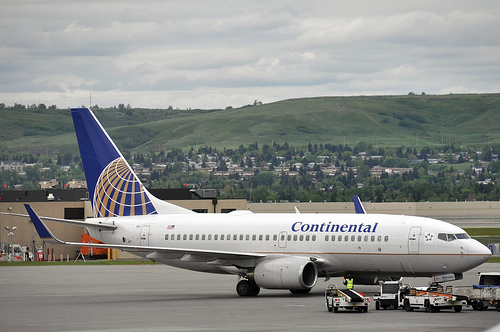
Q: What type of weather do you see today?
A: It is cloudy.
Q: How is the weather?
A: It is cloudy.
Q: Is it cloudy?
A: Yes, it is cloudy.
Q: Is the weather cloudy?
A: Yes, it is cloudy.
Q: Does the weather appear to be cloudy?
A: Yes, it is cloudy.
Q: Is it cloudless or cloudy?
A: It is cloudy.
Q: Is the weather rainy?
A: No, it is cloudy.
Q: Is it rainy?
A: No, it is cloudy.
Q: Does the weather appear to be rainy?
A: No, it is cloudy.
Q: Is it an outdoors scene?
A: Yes, it is outdoors.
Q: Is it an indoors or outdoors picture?
A: It is outdoors.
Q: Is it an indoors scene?
A: No, it is outdoors.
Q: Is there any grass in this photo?
A: Yes, there is grass.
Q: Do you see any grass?
A: Yes, there is grass.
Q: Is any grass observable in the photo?
A: Yes, there is grass.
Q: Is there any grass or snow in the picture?
A: Yes, there is grass.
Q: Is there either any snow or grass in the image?
A: Yes, there is grass.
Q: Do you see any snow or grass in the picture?
A: Yes, there is grass.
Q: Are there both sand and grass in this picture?
A: No, there is grass but no sand.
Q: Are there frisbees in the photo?
A: No, there are no frisbees.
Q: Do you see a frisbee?
A: No, there are no frisbees.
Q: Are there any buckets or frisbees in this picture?
A: No, there are no frisbees or buckets.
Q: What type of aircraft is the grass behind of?
A: The grass is behind the plane.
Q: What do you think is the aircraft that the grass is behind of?
A: The aircraft is an airplane.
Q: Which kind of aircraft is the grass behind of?
A: The grass is behind the plane.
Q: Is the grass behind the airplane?
A: Yes, the grass is behind the airplane.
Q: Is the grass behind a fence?
A: No, the grass is behind the airplane.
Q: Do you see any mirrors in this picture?
A: No, there are no mirrors.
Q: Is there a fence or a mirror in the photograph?
A: No, there are no mirrors or fences.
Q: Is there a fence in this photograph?
A: No, there are no fences.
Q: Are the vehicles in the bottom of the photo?
A: Yes, the vehicles are in the bottom of the image.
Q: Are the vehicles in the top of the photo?
A: No, the vehicles are in the bottom of the image.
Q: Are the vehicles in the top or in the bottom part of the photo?
A: The vehicles are in the bottom of the image.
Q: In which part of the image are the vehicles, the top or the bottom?
A: The vehicles are in the bottom of the image.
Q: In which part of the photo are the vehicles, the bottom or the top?
A: The vehicles are in the bottom of the image.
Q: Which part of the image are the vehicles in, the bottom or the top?
A: The vehicles are in the bottom of the image.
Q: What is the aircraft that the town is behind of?
A: The aircraft is an airplane.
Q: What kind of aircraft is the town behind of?
A: The town is behind the airplane.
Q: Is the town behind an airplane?
A: Yes, the town is behind an airplane.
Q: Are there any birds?
A: No, there are no birds.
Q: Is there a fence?
A: No, there are no fences.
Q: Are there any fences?
A: No, there are no fences.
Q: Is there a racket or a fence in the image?
A: No, there are no fences or rackets.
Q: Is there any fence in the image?
A: No, there are no fences.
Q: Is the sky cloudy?
A: Yes, the sky is cloudy.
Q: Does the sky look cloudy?
A: Yes, the sky is cloudy.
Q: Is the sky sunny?
A: No, the sky is cloudy.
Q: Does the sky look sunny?
A: No, the sky is cloudy.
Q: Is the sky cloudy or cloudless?
A: The sky is cloudy.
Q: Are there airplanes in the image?
A: Yes, there is an airplane.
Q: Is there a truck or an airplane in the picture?
A: Yes, there is an airplane.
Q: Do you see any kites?
A: No, there are no kites.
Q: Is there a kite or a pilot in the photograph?
A: No, there are no kites or pilots.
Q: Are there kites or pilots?
A: No, there are no kites or pilots.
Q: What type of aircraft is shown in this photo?
A: The aircraft is an airplane.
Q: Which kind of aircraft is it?
A: The aircraft is an airplane.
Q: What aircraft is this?
A: This is an airplane.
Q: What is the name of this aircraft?
A: This is an airplane.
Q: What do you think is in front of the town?
A: The plane is in front of the town.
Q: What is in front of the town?
A: The plane is in front of the town.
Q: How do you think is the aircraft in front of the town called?
A: The aircraft is an airplane.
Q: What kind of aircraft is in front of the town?
A: The aircraft is an airplane.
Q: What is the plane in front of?
A: The plane is in front of the town.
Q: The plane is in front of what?
A: The plane is in front of the town.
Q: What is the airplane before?
A: The plane is in front of the town.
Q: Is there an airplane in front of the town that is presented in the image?
A: Yes, there is an airplane in front of the town.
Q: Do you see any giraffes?
A: No, there are no giraffes.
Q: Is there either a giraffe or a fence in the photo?
A: No, there are no giraffes or fences.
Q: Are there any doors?
A: Yes, there is a door.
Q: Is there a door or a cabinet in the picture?
A: Yes, there is a door.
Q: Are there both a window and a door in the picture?
A: Yes, there are both a door and a window.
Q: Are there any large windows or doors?
A: Yes, there is a large door.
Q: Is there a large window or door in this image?
A: Yes, there is a large door.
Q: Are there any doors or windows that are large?
A: Yes, the door is large.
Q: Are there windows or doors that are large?
A: Yes, the door is large.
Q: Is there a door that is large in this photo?
A: Yes, there is a large door.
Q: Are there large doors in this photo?
A: Yes, there is a large door.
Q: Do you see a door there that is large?
A: Yes, there is a door that is large.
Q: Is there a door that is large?
A: Yes, there is a door that is large.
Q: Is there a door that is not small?
A: Yes, there is a large door.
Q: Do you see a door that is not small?
A: Yes, there is a large door.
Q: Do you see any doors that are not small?
A: Yes, there is a large door.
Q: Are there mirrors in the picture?
A: No, there are no mirrors.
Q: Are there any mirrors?
A: No, there are no mirrors.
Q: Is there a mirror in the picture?
A: No, there are no mirrors.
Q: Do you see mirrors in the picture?
A: No, there are no mirrors.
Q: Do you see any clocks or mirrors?
A: No, there are no mirrors or clocks.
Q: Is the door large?
A: Yes, the door is large.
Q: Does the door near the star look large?
A: Yes, the door is large.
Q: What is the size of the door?
A: The door is large.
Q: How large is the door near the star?
A: The door is large.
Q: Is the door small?
A: No, the door is large.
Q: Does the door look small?
A: No, the door is large.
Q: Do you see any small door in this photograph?
A: No, there is a door but it is large.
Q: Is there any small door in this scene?
A: No, there is a door but it is large.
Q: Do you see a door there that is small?
A: No, there is a door but it is large.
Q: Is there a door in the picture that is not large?
A: No, there is a door but it is large.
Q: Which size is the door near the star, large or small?
A: The door is large.